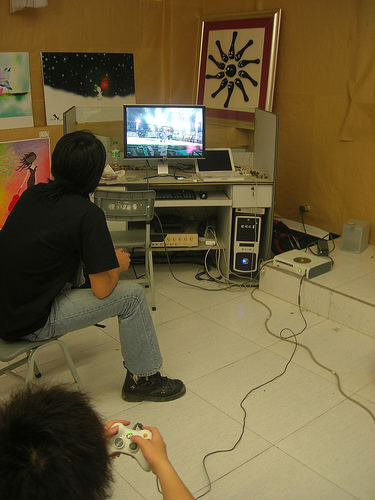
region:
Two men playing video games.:
[0, 127, 190, 495]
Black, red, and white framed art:
[187, 4, 268, 114]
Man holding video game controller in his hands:
[0, 375, 196, 490]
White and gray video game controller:
[105, 420, 150, 468]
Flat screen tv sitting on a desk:
[120, 100, 203, 167]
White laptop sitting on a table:
[189, 146, 241, 178]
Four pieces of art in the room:
[0, 16, 279, 223]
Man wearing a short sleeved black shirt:
[0, 128, 190, 402]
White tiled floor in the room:
[0, 246, 374, 497]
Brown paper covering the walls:
[2, 0, 374, 240]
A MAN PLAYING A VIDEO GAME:
[2, 127, 189, 406]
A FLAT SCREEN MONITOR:
[120, 102, 207, 183]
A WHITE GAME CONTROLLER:
[101, 421, 158, 474]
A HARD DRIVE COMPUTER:
[229, 210, 263, 278]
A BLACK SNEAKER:
[119, 368, 188, 404]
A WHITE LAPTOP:
[193, 145, 249, 184]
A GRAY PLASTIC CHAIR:
[86, 185, 162, 313]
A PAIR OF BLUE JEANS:
[17, 273, 165, 379]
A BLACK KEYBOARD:
[145, 185, 200, 202]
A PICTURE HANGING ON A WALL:
[194, 4, 284, 130]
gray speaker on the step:
[339, 217, 370, 253]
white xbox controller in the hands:
[103, 421, 152, 472]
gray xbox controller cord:
[155, 273, 308, 498]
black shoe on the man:
[118, 360, 188, 403]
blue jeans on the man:
[20, 279, 163, 377]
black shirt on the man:
[0, 181, 121, 342]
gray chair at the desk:
[90, 187, 158, 312]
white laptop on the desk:
[193, 146, 246, 182]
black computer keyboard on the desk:
[135, 186, 197, 201]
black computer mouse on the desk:
[197, 189, 208, 200]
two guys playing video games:
[1, 120, 253, 498]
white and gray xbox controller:
[100, 419, 164, 469]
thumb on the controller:
[126, 428, 145, 447]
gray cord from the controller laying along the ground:
[126, 331, 308, 497]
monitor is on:
[121, 102, 209, 163]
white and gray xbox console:
[273, 242, 331, 281]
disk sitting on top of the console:
[293, 253, 313, 265]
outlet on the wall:
[298, 202, 311, 214]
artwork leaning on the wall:
[40, 47, 144, 127]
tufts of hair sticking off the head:
[7, 375, 94, 401]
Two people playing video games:
[2, 127, 199, 498]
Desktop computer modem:
[230, 214, 261, 274]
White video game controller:
[105, 421, 153, 472]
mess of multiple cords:
[195, 223, 261, 296]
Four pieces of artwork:
[0, 7, 282, 228]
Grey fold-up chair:
[92, 187, 158, 311]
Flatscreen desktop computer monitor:
[119, 103, 205, 177]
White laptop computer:
[193, 146, 243, 180]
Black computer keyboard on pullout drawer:
[152, 187, 194, 197]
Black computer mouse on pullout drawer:
[197, 189, 206, 197]